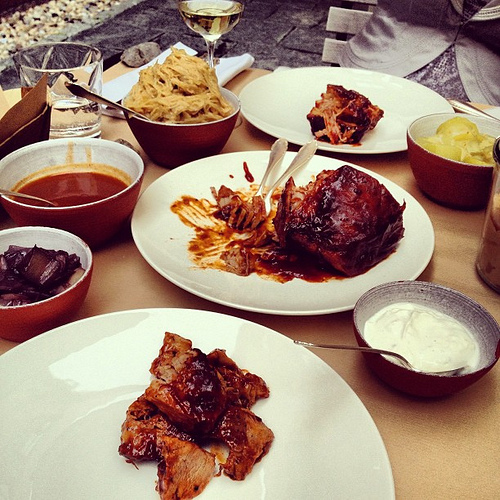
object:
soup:
[11, 173, 129, 208]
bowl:
[0, 141, 145, 246]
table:
[0, 55, 500, 500]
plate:
[131, 149, 435, 316]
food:
[274, 165, 407, 277]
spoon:
[0, 189, 54, 207]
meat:
[119, 331, 271, 500]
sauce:
[183, 359, 223, 414]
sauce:
[171, 172, 351, 283]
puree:
[124, 42, 234, 122]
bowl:
[121, 85, 241, 168]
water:
[48, 100, 101, 129]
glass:
[14, 42, 104, 144]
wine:
[180, 0, 245, 39]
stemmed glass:
[176, 0, 245, 66]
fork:
[229, 138, 289, 230]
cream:
[363, 302, 482, 374]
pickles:
[416, 118, 496, 168]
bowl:
[352, 281, 499, 402]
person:
[339, 0, 499, 107]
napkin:
[99, 39, 253, 120]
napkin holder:
[0, 102, 51, 163]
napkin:
[0, 74, 50, 156]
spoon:
[292, 338, 468, 377]